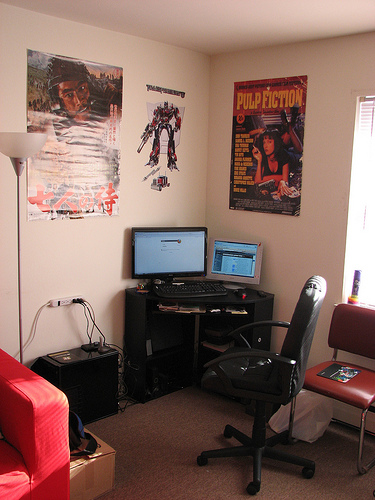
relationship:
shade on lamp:
[2, 128, 47, 164] [1, 131, 47, 365]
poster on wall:
[136, 84, 186, 191] [0, 2, 372, 401]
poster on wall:
[134, 72, 191, 203] [0, 2, 372, 401]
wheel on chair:
[243, 478, 261, 494] [195, 273, 328, 496]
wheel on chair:
[300, 463, 315, 478] [195, 273, 328, 496]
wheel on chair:
[195, 450, 212, 467] [195, 273, 328, 496]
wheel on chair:
[220, 427, 233, 440] [195, 273, 328, 496]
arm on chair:
[232, 348, 295, 363] [197, 344, 298, 398]